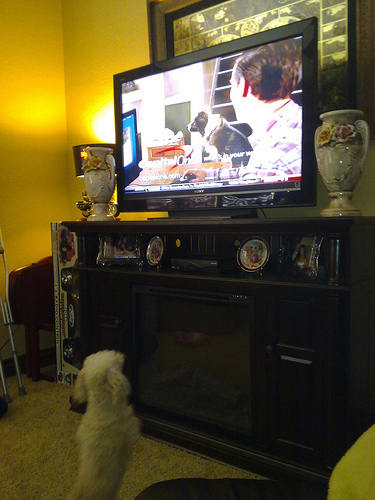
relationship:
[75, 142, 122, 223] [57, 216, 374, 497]
vase on entertainment center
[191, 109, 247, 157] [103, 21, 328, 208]
dog on television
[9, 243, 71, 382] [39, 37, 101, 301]
chair in corner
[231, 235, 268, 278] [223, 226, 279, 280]
plate on shelf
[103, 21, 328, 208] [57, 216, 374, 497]
television on entertainment center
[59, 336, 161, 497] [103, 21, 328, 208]
dog watching television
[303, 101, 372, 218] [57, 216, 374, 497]
vase on entertainment center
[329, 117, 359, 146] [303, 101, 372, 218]
rose on vase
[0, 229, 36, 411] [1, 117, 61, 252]
crutches on wall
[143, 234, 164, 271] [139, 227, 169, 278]
china on shelf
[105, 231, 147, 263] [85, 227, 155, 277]
photo on shelf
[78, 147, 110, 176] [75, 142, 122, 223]
flower on vase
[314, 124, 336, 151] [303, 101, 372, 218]
flower on vase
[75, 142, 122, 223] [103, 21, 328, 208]
vase near television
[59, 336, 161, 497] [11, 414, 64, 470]
dog on carpet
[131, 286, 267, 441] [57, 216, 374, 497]
fireplace in entertainment center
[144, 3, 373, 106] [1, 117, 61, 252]
picture on wall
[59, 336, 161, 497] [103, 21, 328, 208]
dog near television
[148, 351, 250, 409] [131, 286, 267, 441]
logs in fireplace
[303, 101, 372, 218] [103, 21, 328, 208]
vase next to tv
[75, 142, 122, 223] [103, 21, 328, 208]
vase on side of television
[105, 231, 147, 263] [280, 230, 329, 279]
photo in frame